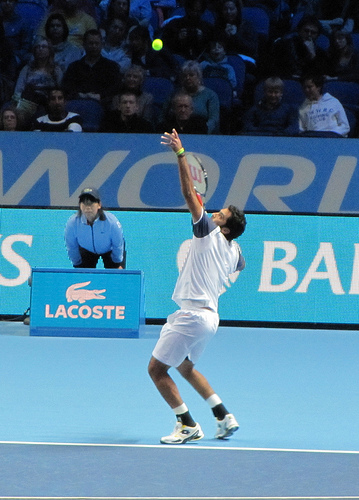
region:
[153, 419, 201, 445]
piece of a tennis outfit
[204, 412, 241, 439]
piece of a tennis outfit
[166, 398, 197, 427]
piece of a tennis outfit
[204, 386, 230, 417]
piece of a tennis outfit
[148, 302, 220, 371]
piece of a tennis outfit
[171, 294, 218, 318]
piece of a tennis outfit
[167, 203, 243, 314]
piece of a tennis outfit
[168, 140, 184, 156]
piece of a tennis outfit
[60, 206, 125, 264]
piece of a tennis outfit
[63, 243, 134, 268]
piece of a tennis outfit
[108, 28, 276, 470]
a player serving the ball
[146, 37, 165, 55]
a yellow tennis ball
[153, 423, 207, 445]
a blue and white tennis shoe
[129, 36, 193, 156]
the hand of a man serving the ball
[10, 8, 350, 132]
spectators watching a tennis match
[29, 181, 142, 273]
an lines woman at a tennis match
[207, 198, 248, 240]
the tennis player watching the ball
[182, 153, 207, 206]
a Wilson tennis racket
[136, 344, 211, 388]
bent knees while serving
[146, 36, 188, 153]
outstretched hand just released the ball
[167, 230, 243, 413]
man serving tennis ball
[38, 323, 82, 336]
blue Lacoste sign behind man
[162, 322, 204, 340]
man wearing white shorts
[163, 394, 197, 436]
man in black and white socks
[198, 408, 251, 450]
man wears white sneakers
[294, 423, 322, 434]
floor of court is blue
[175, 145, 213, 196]
man holding tennis racket up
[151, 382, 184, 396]
man has well defined calves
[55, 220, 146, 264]
person bending over in jacket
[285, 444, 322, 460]
white line on blue court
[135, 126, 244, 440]
man wearing white shirt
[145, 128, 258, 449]
man wearing white shorts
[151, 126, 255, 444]
man wearing tennis shoes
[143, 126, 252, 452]
man holding a racket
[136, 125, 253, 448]
man hitting a ball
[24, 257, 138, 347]
sign on a tennis court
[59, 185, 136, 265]
man wearing a cap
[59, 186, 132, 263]
man wearing a jacket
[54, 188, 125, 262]
man wearing black pants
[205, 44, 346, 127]
people watching tennis match